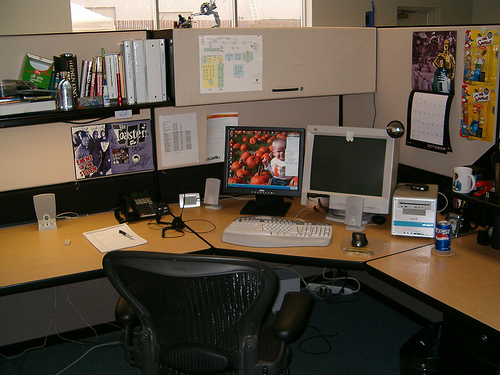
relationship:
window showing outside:
[68, 2, 315, 32] [67, 0, 314, 31]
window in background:
[68, 2, 315, 32] [0, 5, 497, 182]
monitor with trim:
[219, 124, 306, 197] [220, 119, 308, 198]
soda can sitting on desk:
[431, 220, 452, 253] [0, 188, 498, 343]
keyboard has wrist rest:
[220, 210, 334, 252] [219, 229, 333, 255]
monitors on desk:
[221, 117, 398, 217] [1, 178, 498, 329]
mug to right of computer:
[450, 162, 483, 200] [292, 114, 415, 231]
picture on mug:
[451, 169, 460, 190] [450, 162, 483, 200]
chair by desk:
[105, 237, 314, 374] [5, 183, 497, 373]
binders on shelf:
[123, 36, 168, 109] [3, 36, 179, 128]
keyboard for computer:
[222, 216, 334, 248] [216, 112, 461, 274]